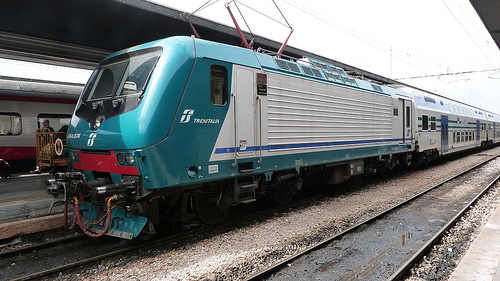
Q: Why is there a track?
A: So the train can travel.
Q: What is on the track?
A: A train.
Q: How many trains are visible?
A: Two.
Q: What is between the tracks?
A: Rocks.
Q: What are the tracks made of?
A: Iron.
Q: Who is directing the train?
A: The engineer.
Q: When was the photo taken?
A: Daytime.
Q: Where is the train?
A: On the track.